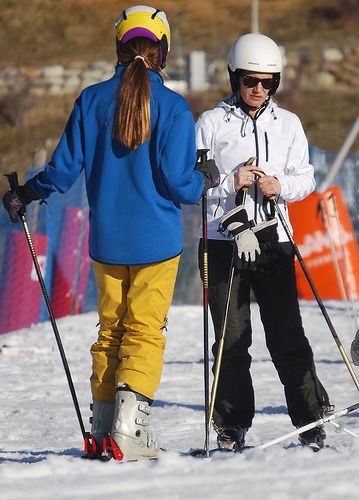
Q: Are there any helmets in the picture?
A: Yes, there is a helmet.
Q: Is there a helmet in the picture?
A: Yes, there is a helmet.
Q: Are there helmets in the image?
A: Yes, there is a helmet.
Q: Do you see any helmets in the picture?
A: Yes, there is a helmet.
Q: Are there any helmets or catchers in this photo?
A: Yes, there is a helmet.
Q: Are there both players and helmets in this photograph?
A: No, there is a helmet but no players.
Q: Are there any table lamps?
A: No, there are no table lamps.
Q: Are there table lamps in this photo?
A: No, there are no table lamps.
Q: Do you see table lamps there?
A: No, there are no table lamps.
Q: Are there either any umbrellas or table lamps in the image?
A: No, there are no table lamps or umbrellas.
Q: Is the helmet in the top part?
A: Yes, the helmet is in the top of the image.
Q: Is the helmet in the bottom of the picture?
A: No, the helmet is in the top of the image.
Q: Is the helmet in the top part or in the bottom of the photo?
A: The helmet is in the top of the image.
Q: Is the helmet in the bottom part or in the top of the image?
A: The helmet is in the top of the image.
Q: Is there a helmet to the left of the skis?
A: Yes, there is a helmet to the left of the skis.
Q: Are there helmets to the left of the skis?
A: Yes, there is a helmet to the left of the skis.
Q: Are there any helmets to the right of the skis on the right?
A: No, the helmet is to the left of the skis.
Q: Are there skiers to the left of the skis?
A: No, there is a helmet to the left of the skis.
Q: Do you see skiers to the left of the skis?
A: No, there is a helmet to the left of the skis.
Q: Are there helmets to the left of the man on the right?
A: Yes, there is a helmet to the left of the man.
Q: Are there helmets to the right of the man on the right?
A: No, the helmet is to the left of the man.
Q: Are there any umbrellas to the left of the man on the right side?
A: No, there is a helmet to the left of the man.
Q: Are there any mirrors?
A: No, there are no mirrors.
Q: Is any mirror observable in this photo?
A: No, there are no mirrors.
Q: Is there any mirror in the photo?
A: No, there are no mirrors.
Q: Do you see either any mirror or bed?
A: No, there are no mirrors or beds.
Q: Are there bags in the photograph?
A: No, there are no bags.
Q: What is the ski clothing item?
A: The clothing item is a jacket.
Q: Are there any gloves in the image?
A: Yes, there are gloves.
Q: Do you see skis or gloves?
A: Yes, there are gloves.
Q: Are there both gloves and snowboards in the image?
A: No, there are gloves but no snowboards.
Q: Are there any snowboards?
A: No, there are no snowboards.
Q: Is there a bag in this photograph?
A: No, there are no bags.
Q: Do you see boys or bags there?
A: No, there are no bags or boys.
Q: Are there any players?
A: No, there are no players.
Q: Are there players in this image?
A: No, there are no players.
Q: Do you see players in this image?
A: No, there are no players.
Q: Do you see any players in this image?
A: No, there are no players.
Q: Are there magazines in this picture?
A: No, there are no magazines.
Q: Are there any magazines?
A: No, there are no magazines.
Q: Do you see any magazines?
A: No, there are no magazines.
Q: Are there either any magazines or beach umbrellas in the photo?
A: No, there are no magazines or beach umbrellas.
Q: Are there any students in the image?
A: No, there are no students.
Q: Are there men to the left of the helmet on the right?
A: Yes, there is a man to the left of the helmet.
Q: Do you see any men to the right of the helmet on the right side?
A: No, the man is to the left of the helmet.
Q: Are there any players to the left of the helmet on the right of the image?
A: No, there is a man to the left of the helmet.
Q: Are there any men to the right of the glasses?
A: No, the man is to the left of the glasses.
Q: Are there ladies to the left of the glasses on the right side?
A: No, there is a man to the left of the glasses.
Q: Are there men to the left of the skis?
A: Yes, there is a man to the left of the skis.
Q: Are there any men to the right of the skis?
A: No, the man is to the left of the skis.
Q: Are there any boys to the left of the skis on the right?
A: No, there is a man to the left of the skis.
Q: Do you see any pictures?
A: No, there are no pictures.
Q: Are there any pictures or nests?
A: No, there are no pictures or nests.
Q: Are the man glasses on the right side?
A: Yes, the glasses are on the right of the image.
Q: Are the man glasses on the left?
A: No, the glasses are on the right of the image.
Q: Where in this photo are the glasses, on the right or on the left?
A: The glasses are on the right of the image.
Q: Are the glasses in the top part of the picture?
A: Yes, the glasses are in the top of the image.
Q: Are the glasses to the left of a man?
A: No, the glasses are to the right of a man.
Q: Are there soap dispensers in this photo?
A: No, there are no soap dispensers.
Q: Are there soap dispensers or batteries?
A: No, there are no soap dispensers or batteries.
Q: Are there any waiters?
A: No, there are no waiters.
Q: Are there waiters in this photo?
A: No, there are no waiters.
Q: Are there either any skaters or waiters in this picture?
A: No, there are no waiters or skaters.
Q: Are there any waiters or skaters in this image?
A: No, there are no waiters or skaters.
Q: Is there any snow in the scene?
A: Yes, there is snow.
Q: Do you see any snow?
A: Yes, there is snow.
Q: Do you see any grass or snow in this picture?
A: Yes, there is snow.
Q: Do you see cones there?
A: No, there are no cones.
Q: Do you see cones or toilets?
A: No, there are no cones or toilets.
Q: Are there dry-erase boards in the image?
A: No, there are no dry-erase boards.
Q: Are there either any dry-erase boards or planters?
A: No, there are no dry-erase boards or planters.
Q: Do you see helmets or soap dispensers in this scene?
A: Yes, there is a helmet.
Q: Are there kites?
A: No, there are no kites.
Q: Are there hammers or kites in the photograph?
A: No, there are no kites or hammers.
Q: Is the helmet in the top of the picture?
A: Yes, the helmet is in the top of the image.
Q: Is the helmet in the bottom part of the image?
A: No, the helmet is in the top of the image.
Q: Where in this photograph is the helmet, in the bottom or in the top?
A: The helmet is in the top of the image.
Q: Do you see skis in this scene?
A: Yes, there are skis.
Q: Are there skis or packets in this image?
A: Yes, there are skis.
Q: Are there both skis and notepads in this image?
A: No, there are skis but no notepads.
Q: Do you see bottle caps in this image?
A: No, there are no bottle caps.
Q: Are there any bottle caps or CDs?
A: No, there are no bottle caps or cds.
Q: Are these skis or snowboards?
A: These are skis.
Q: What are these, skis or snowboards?
A: These are skis.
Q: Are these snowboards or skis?
A: These are skis.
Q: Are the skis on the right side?
A: Yes, the skis are on the right of the image.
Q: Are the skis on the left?
A: No, the skis are on the right of the image.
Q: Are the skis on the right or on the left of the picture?
A: The skis are on the right of the image.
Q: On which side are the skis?
A: The skis are on the right of the image.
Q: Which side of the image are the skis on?
A: The skis are on the right of the image.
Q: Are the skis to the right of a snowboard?
A: No, the skis are to the right of the helmet.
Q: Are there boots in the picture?
A: Yes, there are boots.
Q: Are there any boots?
A: Yes, there are boots.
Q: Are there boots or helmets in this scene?
A: Yes, there are boots.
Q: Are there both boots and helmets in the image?
A: Yes, there are both boots and a helmet.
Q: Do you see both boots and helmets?
A: Yes, there are both boots and a helmet.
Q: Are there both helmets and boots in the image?
A: Yes, there are both boots and a helmet.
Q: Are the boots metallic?
A: Yes, the boots are metallic.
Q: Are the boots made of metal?
A: Yes, the boots are made of metal.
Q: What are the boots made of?
A: The boots are made of metal.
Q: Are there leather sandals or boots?
A: No, there are boots but they are metallic.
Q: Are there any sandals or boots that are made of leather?
A: No, there are boots but they are made of metal.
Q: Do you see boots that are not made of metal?
A: No, there are boots but they are made of metal.